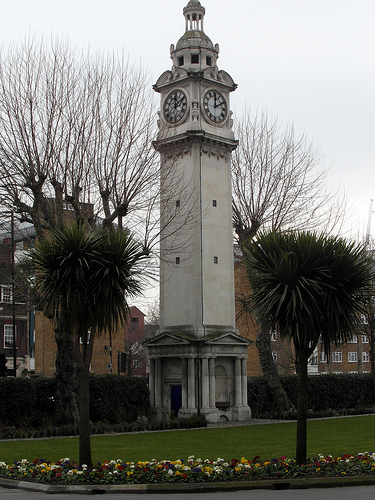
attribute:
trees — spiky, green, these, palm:
[14, 220, 156, 471]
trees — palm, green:
[240, 223, 374, 466]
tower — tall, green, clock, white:
[145, 1, 251, 426]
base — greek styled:
[141, 328, 253, 427]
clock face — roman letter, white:
[200, 85, 230, 127]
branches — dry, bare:
[215, 105, 349, 250]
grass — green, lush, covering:
[2, 411, 374, 474]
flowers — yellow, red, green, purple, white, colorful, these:
[1, 449, 375, 485]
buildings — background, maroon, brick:
[225, 242, 375, 383]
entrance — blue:
[166, 381, 184, 422]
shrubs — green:
[1, 373, 146, 431]